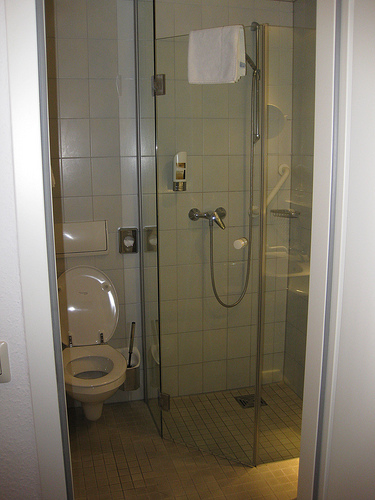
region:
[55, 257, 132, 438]
toilet is white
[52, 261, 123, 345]
lid of toilet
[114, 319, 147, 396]
brush of toilet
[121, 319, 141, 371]
handle of brush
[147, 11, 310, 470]
door of glass is open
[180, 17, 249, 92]
towel is white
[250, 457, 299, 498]
light on floor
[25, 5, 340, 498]
door of bathroom is open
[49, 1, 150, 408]
wall of bathroom is tiled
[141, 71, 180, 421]
two hinges on bathroom door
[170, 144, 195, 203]
Shampoo in stand up shower.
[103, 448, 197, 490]
The brownish bathroom floor tile.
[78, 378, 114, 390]
The toilet seat of a white toliet.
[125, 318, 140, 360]
The handle of a silver toilet brush.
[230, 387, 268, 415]
The grey shower drain of the shower.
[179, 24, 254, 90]
A white towel over the top of the shower door.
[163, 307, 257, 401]
The clear glass of the shower door.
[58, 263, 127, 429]
A white toliet in the bathroom.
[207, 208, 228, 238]
A silver shower head.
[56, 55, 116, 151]
The white wall tile.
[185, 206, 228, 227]
a metal shower faucet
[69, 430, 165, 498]
beige tiles on a bathroom floor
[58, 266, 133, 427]
a white toilet with the seat up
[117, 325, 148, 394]
a container with a plunger inside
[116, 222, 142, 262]
a silver tissue dispenser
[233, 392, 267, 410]
a metal shower drain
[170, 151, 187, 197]
a white and silver soap dispenser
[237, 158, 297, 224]
a white hand rail inside the shower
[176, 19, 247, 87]
a white towel thrown over the top of the shower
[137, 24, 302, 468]
a glass corner shower in a bathroom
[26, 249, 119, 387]
A toilet bowl is visible.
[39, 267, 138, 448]
A toilet bowl is visible.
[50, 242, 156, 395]
A toilet bowl is visible.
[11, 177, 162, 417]
A toilet bowl is visible.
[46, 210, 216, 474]
A toilet bowl is visible.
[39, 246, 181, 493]
A toilet bowl is visible.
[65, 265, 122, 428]
a white toilet in a bathroom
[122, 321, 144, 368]
tip of a toilet brush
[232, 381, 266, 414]
a shower drain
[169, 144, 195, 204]
a soap dispenser on a wall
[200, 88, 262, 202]
metal shower hose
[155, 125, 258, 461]
a shower's glass door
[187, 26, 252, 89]
a white towel hanging on a shower door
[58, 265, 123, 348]
a toilet lid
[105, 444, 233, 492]
brown tiles on a bathroom floor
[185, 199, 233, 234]
a shower handle